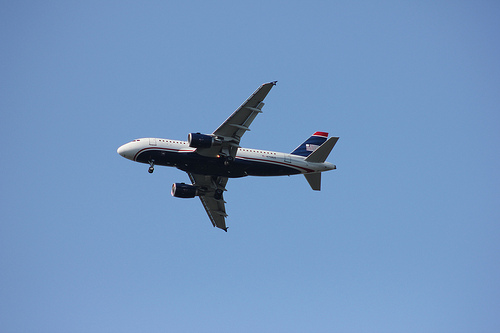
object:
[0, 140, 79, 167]
sky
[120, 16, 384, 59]
blue sky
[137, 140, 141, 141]
windows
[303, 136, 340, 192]
tail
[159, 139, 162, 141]
window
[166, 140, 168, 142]
window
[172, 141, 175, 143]
window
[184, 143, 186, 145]
window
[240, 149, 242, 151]
window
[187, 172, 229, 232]
wing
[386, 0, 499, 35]
sky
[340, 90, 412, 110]
sky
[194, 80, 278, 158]
wing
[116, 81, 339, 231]
jet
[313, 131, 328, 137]
red trim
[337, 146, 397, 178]
no altitude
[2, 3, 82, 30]
sky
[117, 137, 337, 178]
fuselage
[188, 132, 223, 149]
engine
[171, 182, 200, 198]
engine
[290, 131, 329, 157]
tail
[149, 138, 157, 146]
door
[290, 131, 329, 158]
tail fin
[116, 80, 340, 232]
commercial flight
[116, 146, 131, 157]
nose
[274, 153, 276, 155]
windows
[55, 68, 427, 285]
sky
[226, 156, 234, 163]
wheels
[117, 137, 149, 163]
pit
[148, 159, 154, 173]
landing gear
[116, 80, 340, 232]
flight